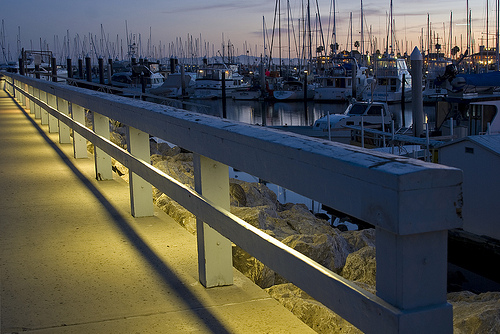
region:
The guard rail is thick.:
[2, 66, 449, 333]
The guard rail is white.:
[2, 65, 468, 332]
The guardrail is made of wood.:
[3, 64, 455, 332]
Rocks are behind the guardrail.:
[143, 139, 498, 332]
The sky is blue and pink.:
[105, 0, 498, 56]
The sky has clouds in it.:
[246, 2, 390, 45]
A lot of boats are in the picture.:
[117, 45, 475, 112]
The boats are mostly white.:
[142, 54, 419, 106]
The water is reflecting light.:
[223, 96, 322, 126]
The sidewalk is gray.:
[10, 186, 136, 333]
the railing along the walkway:
[2, 69, 461, 330]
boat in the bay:
[351, 53, 411, 105]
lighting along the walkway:
[2, 70, 442, 330]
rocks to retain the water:
[228, 173, 375, 332]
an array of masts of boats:
[0, 1, 499, 63]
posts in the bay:
[214, 62, 230, 114]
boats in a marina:
[7, 32, 489, 109]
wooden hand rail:
[202, 98, 464, 238]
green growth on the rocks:
[291, 230, 332, 255]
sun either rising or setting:
[352, 0, 495, 75]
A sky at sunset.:
[346, 24, 484, 75]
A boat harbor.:
[213, 48, 448, 166]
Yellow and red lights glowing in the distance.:
[462, 47, 492, 67]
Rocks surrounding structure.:
[258, 191, 315, 242]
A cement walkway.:
[21, 131, 103, 328]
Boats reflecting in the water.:
[249, 112, 299, 128]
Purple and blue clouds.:
[263, 7, 353, 49]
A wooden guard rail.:
[31, 88, 286, 245]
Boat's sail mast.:
[163, 38, 200, 57]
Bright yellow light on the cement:
[63, 167, 168, 287]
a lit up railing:
[50, 125, 247, 310]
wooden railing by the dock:
[2, 112, 492, 327]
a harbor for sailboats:
[22, 4, 474, 173]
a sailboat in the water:
[276, 10, 376, 110]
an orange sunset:
[341, 2, 498, 51]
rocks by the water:
[238, 177, 345, 259]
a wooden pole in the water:
[206, 57, 236, 109]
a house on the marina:
[392, 100, 498, 260]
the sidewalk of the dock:
[7, 154, 129, 311]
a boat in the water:
[299, 82, 437, 147]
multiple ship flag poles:
[39, 10, 496, 71]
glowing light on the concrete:
[102, 215, 267, 327]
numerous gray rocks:
[248, 209, 450, 332]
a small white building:
[440, 120, 498, 217]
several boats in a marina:
[67, 48, 496, 96]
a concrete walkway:
[0, 88, 172, 330]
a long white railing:
[1, 62, 424, 328]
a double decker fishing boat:
[366, 45, 414, 105]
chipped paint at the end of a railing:
[446, 185, 468, 222]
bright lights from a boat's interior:
[474, 51, 492, 69]